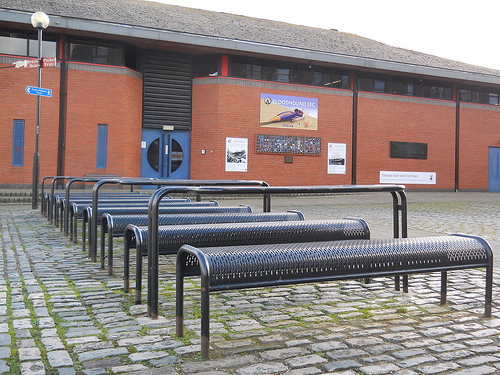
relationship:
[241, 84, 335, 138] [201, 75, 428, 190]
sign on wall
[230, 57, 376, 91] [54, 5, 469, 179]
windows on building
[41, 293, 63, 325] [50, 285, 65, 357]
grass in crevice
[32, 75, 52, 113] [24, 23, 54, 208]
post on pole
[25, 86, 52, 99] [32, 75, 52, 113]
post on post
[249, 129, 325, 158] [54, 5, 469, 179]
mosaic on building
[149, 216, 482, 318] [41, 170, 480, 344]
benches in row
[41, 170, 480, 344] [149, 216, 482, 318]
row of benches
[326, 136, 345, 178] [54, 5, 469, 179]
sign on building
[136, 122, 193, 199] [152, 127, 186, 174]
door with windows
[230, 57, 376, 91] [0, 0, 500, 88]
windows on roof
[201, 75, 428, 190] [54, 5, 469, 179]
signs on building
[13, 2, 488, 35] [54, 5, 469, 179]
roof of building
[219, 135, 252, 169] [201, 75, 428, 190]
poster on wall